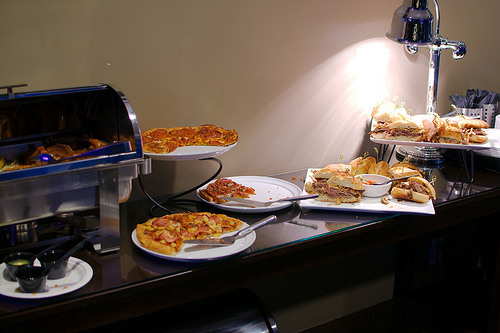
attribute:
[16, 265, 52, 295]
cup — black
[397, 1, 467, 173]
light — above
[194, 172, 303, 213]
plate — white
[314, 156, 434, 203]
sandwiches — small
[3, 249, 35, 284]
cup — three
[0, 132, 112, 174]
food — inside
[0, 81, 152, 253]
tray — warming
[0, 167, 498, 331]
table — glass top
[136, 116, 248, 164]
slices — missing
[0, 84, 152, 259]
oven — roasting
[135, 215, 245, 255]
food — warmed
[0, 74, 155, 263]
tool — warming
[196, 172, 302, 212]
tray — white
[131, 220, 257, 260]
plate — white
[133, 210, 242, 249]
pizza — small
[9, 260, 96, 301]
plate — white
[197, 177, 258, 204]
pizza — single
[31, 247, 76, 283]
condiment cup — black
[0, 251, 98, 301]
plate — white